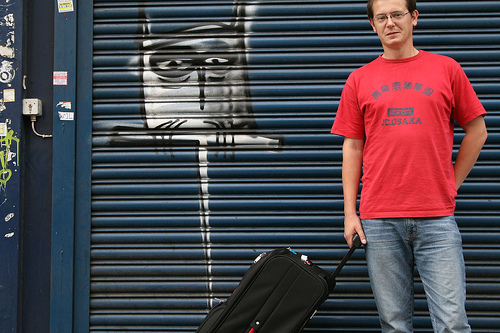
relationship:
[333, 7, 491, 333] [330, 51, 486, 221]
man wearing t-shirt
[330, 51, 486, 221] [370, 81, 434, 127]
t-shirt has writing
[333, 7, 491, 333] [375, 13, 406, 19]
man wearing glasses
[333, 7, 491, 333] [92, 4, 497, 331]
man next to garage door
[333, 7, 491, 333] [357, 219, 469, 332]
man wearing jeans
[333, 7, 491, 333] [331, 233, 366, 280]
man holding handle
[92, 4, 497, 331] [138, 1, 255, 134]
garage door has owl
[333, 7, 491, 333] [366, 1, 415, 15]
man has hair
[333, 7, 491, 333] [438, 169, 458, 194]
man has hand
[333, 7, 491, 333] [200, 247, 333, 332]
man holding suitcase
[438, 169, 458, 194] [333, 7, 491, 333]
hand behind man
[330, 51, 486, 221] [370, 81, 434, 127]
shirt has writing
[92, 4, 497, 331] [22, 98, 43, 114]
garage door has electrical switch